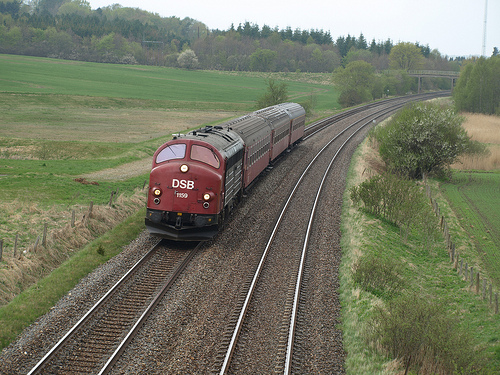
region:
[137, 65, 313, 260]
Red train moving on train track.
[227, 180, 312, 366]
Empty train track next to red train.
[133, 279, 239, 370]
Pebbles between and on side of train tracks.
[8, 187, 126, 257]
Wire fence next to train tracks.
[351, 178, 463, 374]
Scrub bush growing next to train tracks.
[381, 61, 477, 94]
Overpass above train tracks.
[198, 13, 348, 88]
Trees growing next to overpass.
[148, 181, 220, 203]
Headlights on front of train.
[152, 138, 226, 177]
Windows on front of train.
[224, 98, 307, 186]
Three train cars attached to engine.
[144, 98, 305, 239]
a train on a track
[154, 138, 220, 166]
windshield on front of train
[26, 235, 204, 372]
empty track in front of train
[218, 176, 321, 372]
second set of train tracks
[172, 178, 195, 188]
"DSB" on front of train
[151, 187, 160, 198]
light on right side of train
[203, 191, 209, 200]
light on left side of train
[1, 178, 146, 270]
wooden fence post next to train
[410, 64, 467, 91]
bridge in the background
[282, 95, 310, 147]
last car attached to engine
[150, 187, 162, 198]
The left headlight on the train.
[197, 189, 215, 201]
The right headlight on the train.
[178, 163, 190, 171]
The center headlight on the train.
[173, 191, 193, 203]
The numbers on the front of the train.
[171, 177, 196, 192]
The letters on the front of the train.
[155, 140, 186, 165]
The left window on the train.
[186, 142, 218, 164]
The right window on the train.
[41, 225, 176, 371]
The tracks in front of the train.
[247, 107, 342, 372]
The tracks to the right of the train.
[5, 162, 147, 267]
The wooden poles in the grassy area to the left of the train.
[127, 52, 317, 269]
A red train.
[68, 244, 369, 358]
Two sets of train tracks.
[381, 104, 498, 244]
A tree and planted crops.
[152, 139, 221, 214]
The front of the train has white letters.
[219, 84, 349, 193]
The train has three cars.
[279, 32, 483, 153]
The tracks curve under a bridge.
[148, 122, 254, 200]
The train engine has two forward facing windows.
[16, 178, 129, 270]
Wooden fence posts partially covered with dry grass.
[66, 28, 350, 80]
A stand of deciduous trees.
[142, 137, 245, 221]
The engine has three headlights.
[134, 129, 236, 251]
red train on tracks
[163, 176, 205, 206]
train with dsb on front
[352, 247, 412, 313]
green grass on side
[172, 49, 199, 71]
trees in background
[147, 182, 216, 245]
lights on front of train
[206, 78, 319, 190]
three cars on train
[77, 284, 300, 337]
two tracks in field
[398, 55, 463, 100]
bridge over train track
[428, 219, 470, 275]
wooden fence over grass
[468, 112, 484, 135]
dead grass in patch